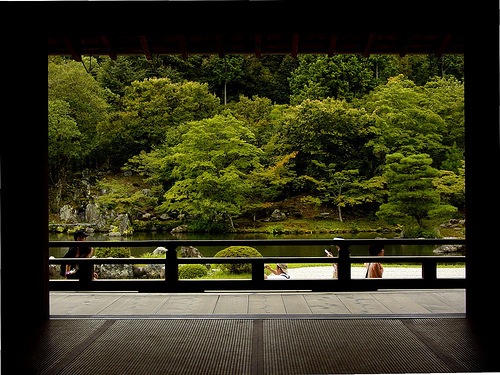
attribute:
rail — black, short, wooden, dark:
[50, 239, 476, 296]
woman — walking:
[363, 242, 386, 281]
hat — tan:
[335, 236, 346, 241]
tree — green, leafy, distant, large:
[122, 109, 297, 235]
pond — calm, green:
[19, 226, 473, 265]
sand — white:
[267, 265, 469, 281]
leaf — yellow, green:
[291, 151, 298, 158]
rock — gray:
[113, 214, 134, 234]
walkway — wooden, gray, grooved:
[47, 289, 467, 319]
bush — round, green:
[211, 244, 263, 270]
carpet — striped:
[1, 318, 499, 373]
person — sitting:
[265, 264, 291, 283]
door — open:
[41, 44, 472, 324]